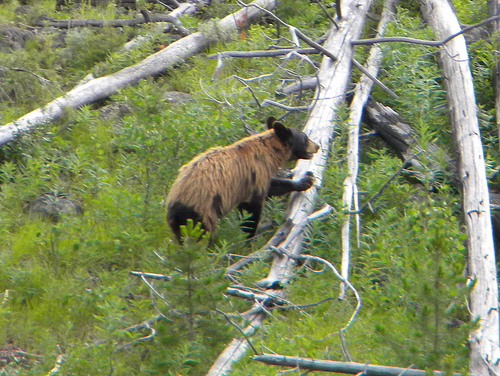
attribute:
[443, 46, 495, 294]
log — rotting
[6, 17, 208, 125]
tree — fallen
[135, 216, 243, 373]
tree — evergreen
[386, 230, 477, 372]
tree — evergreen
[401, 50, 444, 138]
tree — evergreen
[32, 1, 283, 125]
tree — evergreen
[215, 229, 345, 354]
tree trunk — dead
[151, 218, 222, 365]
short pine — green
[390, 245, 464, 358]
short pine — green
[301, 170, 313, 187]
paws — wet 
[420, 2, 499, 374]
log — sun bleached, fallen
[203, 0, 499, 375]
tree — fallen 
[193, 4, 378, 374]
log — sun bleached, down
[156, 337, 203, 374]
plant — green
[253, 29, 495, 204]
log — black, tan, fallen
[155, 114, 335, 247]
bear — one 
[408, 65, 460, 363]
weed — leafy , green , tall 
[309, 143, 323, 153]
nose — black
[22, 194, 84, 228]
stone — big , lumpy , grey 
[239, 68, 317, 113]
branch — gnarly , sun bleached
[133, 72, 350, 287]
bear — black, fur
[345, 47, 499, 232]
tree — fallen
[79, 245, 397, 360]
branches — broken, dead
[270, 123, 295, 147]
ear — black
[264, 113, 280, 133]
ear — black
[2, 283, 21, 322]
plant — yellow